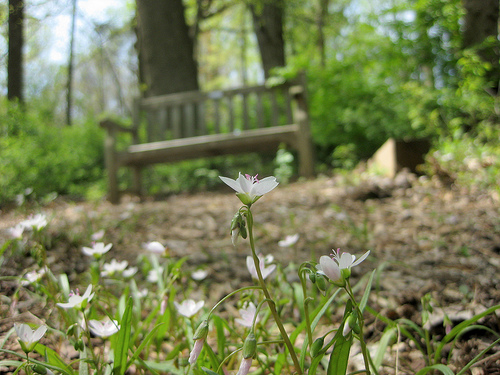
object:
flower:
[219, 173, 304, 375]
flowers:
[2, 319, 51, 374]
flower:
[317, 249, 372, 375]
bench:
[97, 70, 312, 204]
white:
[240, 182, 255, 191]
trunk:
[133, 2, 204, 136]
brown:
[143, 11, 182, 82]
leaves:
[2, 97, 109, 208]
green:
[16, 143, 53, 174]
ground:
[4, 185, 499, 315]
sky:
[2, 2, 137, 123]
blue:
[29, 2, 55, 18]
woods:
[1, 1, 498, 133]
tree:
[247, 2, 286, 81]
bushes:
[285, 11, 499, 162]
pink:
[243, 173, 250, 181]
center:
[243, 173, 260, 185]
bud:
[230, 213, 247, 248]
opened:
[82, 242, 115, 258]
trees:
[135, 2, 197, 143]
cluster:
[13, 270, 130, 370]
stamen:
[66, 289, 82, 303]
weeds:
[413, 116, 499, 203]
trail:
[2, 211, 497, 284]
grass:
[7, 148, 497, 217]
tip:
[230, 226, 240, 247]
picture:
[2, 0, 499, 374]